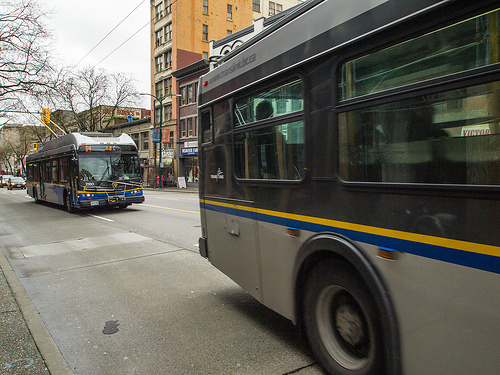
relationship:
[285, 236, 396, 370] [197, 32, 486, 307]
tire on bus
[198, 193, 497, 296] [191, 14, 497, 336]
stripe on bus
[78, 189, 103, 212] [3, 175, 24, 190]
headlights on car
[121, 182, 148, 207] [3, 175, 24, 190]
headlights on car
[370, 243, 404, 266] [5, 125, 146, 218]
light on side of bus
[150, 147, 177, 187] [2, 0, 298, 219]
store in background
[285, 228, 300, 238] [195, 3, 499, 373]
reflector on side of bus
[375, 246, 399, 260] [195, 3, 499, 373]
reflector on side of bus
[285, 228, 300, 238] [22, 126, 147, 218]
reflector on side of bus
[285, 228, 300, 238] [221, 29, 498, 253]
reflector on side of bus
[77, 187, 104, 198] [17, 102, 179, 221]
reflector on side of bus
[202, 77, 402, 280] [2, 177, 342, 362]
bus on road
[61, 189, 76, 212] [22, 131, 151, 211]
wheel of a bus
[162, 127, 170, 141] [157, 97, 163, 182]
sign on pole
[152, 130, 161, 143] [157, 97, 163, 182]
sign on pole